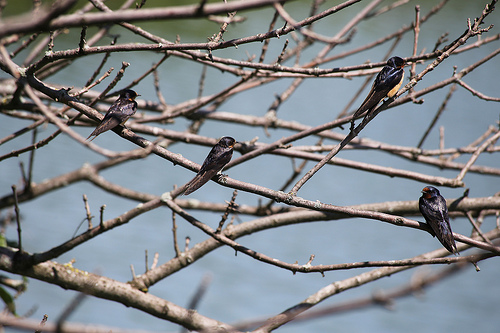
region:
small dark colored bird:
[176, 131, 239, 200]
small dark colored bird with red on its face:
[415, 187, 462, 255]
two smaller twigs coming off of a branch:
[75, 193, 109, 233]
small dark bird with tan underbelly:
[350, 54, 410, 114]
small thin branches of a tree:
[2, 0, 404, 98]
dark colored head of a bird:
[418, 181, 439, 196]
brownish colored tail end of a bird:
[183, 168, 218, 203]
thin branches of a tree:
[168, 20, 369, 89]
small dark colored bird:
[417, 182, 456, 254]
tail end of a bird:
[86, 110, 117, 137]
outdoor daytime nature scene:
[4, 3, 499, 324]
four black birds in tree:
[76, 46, 476, 252]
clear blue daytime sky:
[2, 0, 498, 321]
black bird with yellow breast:
[346, 50, 423, 127]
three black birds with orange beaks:
[86, 81, 468, 255]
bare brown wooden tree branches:
[4, 4, 498, 326]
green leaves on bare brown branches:
[1, 167, 44, 329]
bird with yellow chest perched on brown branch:
[268, 2, 498, 210]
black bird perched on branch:
[85, 80, 159, 144]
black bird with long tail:
[175, 127, 248, 198]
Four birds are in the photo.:
[74, 41, 481, 263]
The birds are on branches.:
[72, 37, 479, 257]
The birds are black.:
[75, 42, 480, 256]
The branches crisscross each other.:
[0, 2, 497, 332]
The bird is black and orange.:
[339, 47, 424, 129]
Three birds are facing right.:
[80, 43, 423, 200]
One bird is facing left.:
[400, 173, 472, 264]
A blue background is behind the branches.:
[0, 89, 498, 331]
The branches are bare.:
[0, 168, 435, 331]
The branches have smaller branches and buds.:
[68, 187, 110, 241]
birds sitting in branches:
[75, 36, 470, 294]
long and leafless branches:
[95, 80, 385, 302]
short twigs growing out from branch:
[75, 191, 165, 231]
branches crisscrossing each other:
[80, 72, 420, 289]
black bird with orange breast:
[291, 30, 481, 135]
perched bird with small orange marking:
[76, 80, 151, 145]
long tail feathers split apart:
[410, 175, 465, 260]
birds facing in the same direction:
[77, 40, 417, 201]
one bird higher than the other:
[336, 40, 461, 265]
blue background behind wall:
[75, 56, 461, 271]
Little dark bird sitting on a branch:
[415, 179, 459, 259]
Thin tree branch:
[55, 20, 336, 55]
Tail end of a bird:
[186, 168, 213, 199]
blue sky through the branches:
[215, 261, 270, 317]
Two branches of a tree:
[258, 184, 415, 232]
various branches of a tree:
[31, 158, 187, 285]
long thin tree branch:
[38, 0, 369, 67]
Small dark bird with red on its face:
[418, 182, 462, 254]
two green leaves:
[0, 267, 26, 319]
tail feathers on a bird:
[90, 113, 119, 142]